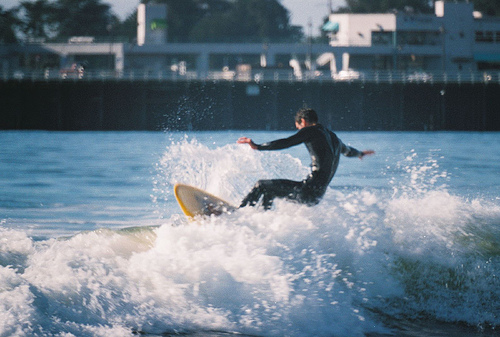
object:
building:
[317, 8, 484, 84]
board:
[172, 178, 222, 221]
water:
[14, 142, 439, 329]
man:
[177, 89, 371, 227]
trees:
[13, 2, 294, 58]